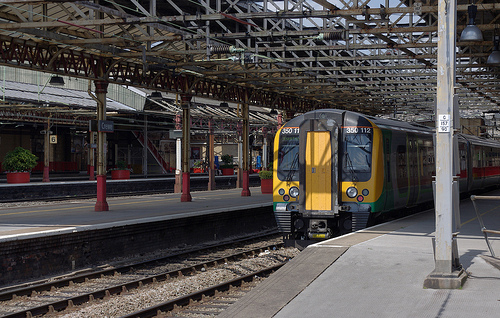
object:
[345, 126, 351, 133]
number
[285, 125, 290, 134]
number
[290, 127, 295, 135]
number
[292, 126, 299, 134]
number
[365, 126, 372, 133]
number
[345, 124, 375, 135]
number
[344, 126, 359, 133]
number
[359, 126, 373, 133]
number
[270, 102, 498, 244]
train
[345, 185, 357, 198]
headlight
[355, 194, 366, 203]
light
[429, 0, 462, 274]
pole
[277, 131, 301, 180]
window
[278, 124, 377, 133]
stripe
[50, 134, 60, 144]
sign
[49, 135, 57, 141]
number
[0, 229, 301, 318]
train tracks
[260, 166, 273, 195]
plant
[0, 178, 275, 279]
platform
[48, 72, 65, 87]
light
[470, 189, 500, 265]
railing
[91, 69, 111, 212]
post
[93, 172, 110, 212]
base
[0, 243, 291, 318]
gravel